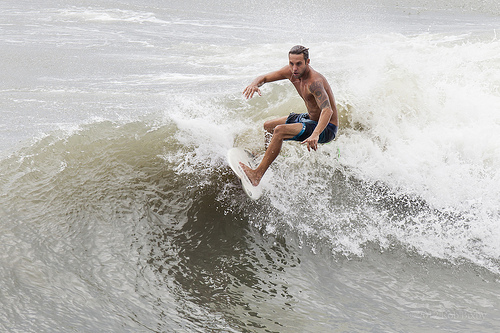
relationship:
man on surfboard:
[238, 45, 343, 185] [216, 128, 260, 195]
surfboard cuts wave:
[216, 128, 260, 195] [48, 105, 499, 284]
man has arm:
[238, 45, 343, 185] [307, 78, 333, 150]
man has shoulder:
[238, 45, 343, 185] [307, 77, 325, 95]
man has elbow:
[238, 45, 343, 185] [320, 103, 334, 121]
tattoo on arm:
[306, 78, 330, 110] [307, 78, 333, 150]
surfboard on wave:
[216, 128, 260, 195] [48, 105, 499, 284]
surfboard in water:
[216, 128, 260, 195] [7, 3, 495, 332]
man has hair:
[238, 45, 343, 185] [290, 45, 310, 62]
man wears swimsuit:
[238, 45, 343, 185] [284, 112, 335, 149]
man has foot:
[238, 45, 343, 185] [231, 153, 269, 193]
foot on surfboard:
[231, 153, 269, 193] [216, 128, 260, 195]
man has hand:
[238, 45, 343, 185] [244, 87, 265, 100]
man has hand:
[238, 45, 343, 185] [301, 134, 319, 151]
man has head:
[238, 45, 343, 185] [287, 47, 308, 77]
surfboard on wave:
[216, 128, 260, 195] [9, 42, 497, 316]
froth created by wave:
[382, 85, 487, 221] [8, 57, 498, 207]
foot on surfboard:
[231, 153, 269, 193] [216, 139, 269, 200]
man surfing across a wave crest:
[238, 45, 343, 185] [342, 49, 452, 186]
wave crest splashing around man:
[174, 83, 499, 265] [238, 45, 343, 185]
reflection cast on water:
[155, 152, 300, 331] [84, 146, 376, 323]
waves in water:
[326, 117, 483, 255] [7, 3, 495, 332]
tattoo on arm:
[306, 78, 330, 110] [301, 81, 333, 151]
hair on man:
[290, 45, 308, 62] [238, 45, 343, 185]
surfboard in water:
[216, 128, 260, 195] [60, 93, 442, 295]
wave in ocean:
[9, 42, 497, 316] [2, 0, 499, 327]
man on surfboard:
[238, 45, 343, 185] [225, 142, 262, 207]